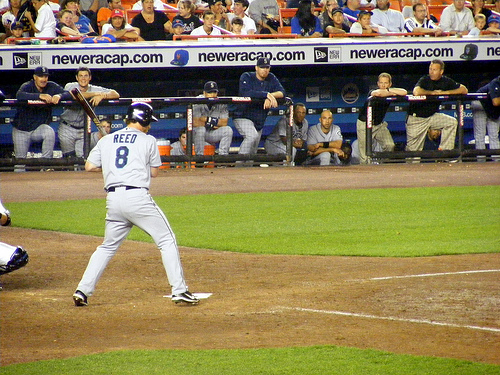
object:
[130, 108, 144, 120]
light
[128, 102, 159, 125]
helmet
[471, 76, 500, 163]
player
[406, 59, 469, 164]
player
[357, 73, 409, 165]
player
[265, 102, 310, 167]
player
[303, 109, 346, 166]
player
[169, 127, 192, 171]
players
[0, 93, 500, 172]
fence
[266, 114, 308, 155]
shirt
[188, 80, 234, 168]
people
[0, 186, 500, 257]
grass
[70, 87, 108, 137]
bat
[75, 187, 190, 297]
guys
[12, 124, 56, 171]
pants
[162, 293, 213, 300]
home plate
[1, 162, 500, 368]
dirt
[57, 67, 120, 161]
people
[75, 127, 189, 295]
uniform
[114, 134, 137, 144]
name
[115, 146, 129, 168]
number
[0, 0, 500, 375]
base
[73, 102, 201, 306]
batter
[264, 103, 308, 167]
players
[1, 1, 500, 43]
fans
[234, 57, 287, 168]
man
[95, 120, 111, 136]
hand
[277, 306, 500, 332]
line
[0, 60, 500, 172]
dug out